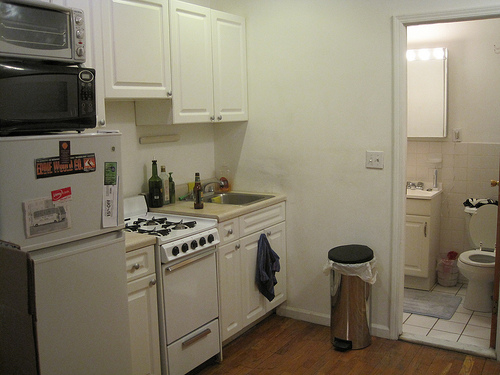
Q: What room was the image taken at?
A: It was taken at the kitchen.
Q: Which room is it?
A: It is a kitchen.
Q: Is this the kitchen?
A: Yes, it is the kitchen.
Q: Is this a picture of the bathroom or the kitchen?
A: It is showing the kitchen.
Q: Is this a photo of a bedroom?
A: No, the picture is showing a kitchen.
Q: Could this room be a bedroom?
A: No, it is a kitchen.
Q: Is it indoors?
A: Yes, it is indoors.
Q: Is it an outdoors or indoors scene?
A: It is indoors.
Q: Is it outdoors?
A: No, it is indoors.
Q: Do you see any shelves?
A: No, there are no shelves.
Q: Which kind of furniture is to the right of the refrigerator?
A: The pieces of furniture are cupboards.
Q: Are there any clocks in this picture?
A: No, there are no clocks.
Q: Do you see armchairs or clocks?
A: No, there are no clocks or armchairs.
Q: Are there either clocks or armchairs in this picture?
A: No, there are no clocks or armchairs.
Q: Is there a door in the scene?
A: Yes, there is a door.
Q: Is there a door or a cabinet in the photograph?
A: Yes, there is a door.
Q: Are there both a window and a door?
A: No, there is a door but no windows.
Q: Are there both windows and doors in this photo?
A: No, there is a door but no windows.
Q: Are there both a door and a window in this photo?
A: No, there is a door but no windows.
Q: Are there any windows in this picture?
A: No, there are no windows.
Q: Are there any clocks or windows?
A: No, there are no windows or clocks.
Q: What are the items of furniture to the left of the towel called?
A: The pieces of furniture are cupboards.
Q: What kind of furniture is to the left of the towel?
A: The pieces of furniture are cupboards.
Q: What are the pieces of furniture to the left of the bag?
A: The pieces of furniture are cupboards.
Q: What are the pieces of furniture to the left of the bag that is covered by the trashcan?
A: The pieces of furniture are cupboards.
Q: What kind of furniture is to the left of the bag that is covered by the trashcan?
A: The pieces of furniture are cupboards.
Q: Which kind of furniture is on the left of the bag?
A: The pieces of furniture are cupboards.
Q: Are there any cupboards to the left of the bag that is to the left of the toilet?
A: Yes, there are cupboards to the left of the bag.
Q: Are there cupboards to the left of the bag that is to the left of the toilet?
A: Yes, there are cupboards to the left of the bag.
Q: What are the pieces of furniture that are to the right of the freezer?
A: The pieces of furniture are cupboards.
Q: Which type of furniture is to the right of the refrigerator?
A: The pieces of furniture are cupboards.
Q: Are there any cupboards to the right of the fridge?
A: Yes, there are cupboards to the right of the fridge.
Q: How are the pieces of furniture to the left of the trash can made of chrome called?
A: The pieces of furniture are cupboards.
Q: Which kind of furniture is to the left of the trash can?
A: The pieces of furniture are cupboards.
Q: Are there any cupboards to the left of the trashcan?
A: Yes, there are cupboards to the left of the trashcan.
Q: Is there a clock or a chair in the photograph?
A: No, there are no chairs or clocks.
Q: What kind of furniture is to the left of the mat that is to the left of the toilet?
A: The piece of furniture is a cupboard.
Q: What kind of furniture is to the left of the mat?
A: The piece of furniture is a cupboard.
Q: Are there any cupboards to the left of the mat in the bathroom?
A: Yes, there is a cupboard to the left of the mat.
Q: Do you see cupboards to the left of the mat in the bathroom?
A: Yes, there is a cupboard to the left of the mat.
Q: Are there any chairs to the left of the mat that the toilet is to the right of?
A: No, there is a cupboard to the left of the mat.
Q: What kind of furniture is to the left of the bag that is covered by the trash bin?
A: The piece of furniture is a cupboard.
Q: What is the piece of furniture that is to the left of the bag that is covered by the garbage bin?
A: The piece of furniture is a cupboard.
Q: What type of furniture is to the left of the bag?
A: The piece of furniture is a cupboard.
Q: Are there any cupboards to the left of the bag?
A: Yes, there is a cupboard to the left of the bag.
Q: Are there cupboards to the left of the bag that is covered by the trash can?
A: Yes, there is a cupboard to the left of the bag.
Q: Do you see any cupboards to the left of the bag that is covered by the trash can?
A: Yes, there is a cupboard to the left of the bag.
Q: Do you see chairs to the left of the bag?
A: No, there is a cupboard to the left of the bag.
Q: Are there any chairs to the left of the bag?
A: No, there is a cupboard to the left of the bag.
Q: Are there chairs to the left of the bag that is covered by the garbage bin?
A: No, there is a cupboard to the left of the bag.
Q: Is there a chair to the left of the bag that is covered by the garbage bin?
A: No, there is a cupboard to the left of the bag.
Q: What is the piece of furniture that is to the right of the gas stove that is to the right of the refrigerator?
A: The piece of furniture is a cupboard.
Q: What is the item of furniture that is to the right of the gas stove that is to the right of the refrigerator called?
A: The piece of furniture is a cupboard.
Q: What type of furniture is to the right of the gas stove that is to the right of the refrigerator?
A: The piece of furniture is a cupboard.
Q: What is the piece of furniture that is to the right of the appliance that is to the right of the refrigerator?
A: The piece of furniture is a cupboard.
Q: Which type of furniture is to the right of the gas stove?
A: The piece of furniture is a cupboard.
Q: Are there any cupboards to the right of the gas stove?
A: Yes, there is a cupboard to the right of the gas stove.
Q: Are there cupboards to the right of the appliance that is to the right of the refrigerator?
A: Yes, there is a cupboard to the right of the gas stove.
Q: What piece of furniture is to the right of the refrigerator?
A: The piece of furniture is a cupboard.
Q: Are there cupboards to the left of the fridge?
A: No, the cupboard is to the right of the fridge.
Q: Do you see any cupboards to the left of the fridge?
A: No, the cupboard is to the right of the fridge.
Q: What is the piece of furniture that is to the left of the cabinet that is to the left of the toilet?
A: The piece of furniture is a cupboard.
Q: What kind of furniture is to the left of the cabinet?
A: The piece of furniture is a cupboard.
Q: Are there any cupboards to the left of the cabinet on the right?
A: Yes, there is a cupboard to the left of the cabinet.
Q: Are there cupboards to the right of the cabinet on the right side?
A: No, the cupboard is to the left of the cabinet.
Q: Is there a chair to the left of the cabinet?
A: No, there is a cupboard to the left of the cabinet.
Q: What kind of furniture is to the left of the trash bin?
A: The piece of furniture is a cupboard.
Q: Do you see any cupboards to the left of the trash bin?
A: Yes, there is a cupboard to the left of the trash bin.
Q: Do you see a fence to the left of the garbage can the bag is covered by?
A: No, there is a cupboard to the left of the trash can.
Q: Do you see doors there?
A: Yes, there is a door.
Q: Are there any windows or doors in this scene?
A: Yes, there is a door.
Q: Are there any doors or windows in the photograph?
A: Yes, there is a door.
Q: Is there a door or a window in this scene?
A: Yes, there is a door.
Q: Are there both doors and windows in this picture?
A: No, there is a door but no windows.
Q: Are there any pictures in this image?
A: No, there are no pictures.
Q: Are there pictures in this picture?
A: No, there are no pictures.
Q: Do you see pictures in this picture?
A: No, there are no pictures.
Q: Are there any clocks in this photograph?
A: No, there are no clocks.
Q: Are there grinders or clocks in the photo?
A: No, there are no clocks or grinders.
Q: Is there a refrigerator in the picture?
A: Yes, there is a refrigerator.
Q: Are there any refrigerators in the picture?
A: Yes, there is a refrigerator.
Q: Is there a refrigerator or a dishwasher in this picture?
A: Yes, there is a refrigerator.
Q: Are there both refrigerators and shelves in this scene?
A: No, there is a refrigerator but no shelves.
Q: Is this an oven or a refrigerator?
A: This is a refrigerator.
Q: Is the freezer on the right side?
A: No, the freezer is on the left of the image.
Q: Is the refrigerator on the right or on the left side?
A: The refrigerator is on the left of the image.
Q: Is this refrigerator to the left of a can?
A: No, the refrigerator is to the left of a bottle.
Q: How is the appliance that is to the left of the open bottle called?
A: The appliance is a refrigerator.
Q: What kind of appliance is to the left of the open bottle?
A: The appliance is a refrigerator.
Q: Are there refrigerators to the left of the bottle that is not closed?
A: Yes, there is a refrigerator to the left of the bottle.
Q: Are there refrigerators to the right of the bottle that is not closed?
A: No, the refrigerator is to the left of the bottle.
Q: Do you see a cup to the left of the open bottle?
A: No, there is a refrigerator to the left of the bottle.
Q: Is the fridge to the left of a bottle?
A: Yes, the fridge is to the left of a bottle.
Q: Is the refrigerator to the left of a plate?
A: No, the refrigerator is to the left of a bottle.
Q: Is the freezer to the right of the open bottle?
A: No, the freezer is to the left of the bottle.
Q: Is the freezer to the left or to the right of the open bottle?
A: The freezer is to the left of the bottle.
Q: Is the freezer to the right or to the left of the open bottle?
A: The freezer is to the left of the bottle.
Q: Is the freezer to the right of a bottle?
A: No, the freezer is to the left of a bottle.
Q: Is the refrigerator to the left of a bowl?
A: No, the refrigerator is to the left of a bottle.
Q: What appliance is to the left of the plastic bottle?
A: The appliance is a refrigerator.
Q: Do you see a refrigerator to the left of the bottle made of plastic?
A: Yes, there is a refrigerator to the left of the bottle.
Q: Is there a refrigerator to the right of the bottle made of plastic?
A: No, the refrigerator is to the left of the bottle.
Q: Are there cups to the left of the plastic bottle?
A: No, there is a refrigerator to the left of the bottle.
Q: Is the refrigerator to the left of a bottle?
A: Yes, the refrigerator is to the left of a bottle.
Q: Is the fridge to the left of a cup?
A: No, the fridge is to the left of a bottle.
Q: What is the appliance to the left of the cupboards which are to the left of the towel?
A: The appliance is a refrigerator.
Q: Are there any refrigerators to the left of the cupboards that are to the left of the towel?
A: Yes, there is a refrigerator to the left of the cupboards.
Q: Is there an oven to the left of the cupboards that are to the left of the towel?
A: No, there is a refrigerator to the left of the cupboards.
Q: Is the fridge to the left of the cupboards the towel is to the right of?
A: Yes, the fridge is to the left of the cupboards.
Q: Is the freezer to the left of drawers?
A: No, the freezer is to the left of the cupboards.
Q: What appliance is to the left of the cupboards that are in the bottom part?
A: The appliance is a refrigerator.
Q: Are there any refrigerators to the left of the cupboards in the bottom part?
A: Yes, there is a refrigerator to the left of the cupboards.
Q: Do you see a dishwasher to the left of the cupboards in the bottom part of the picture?
A: No, there is a refrigerator to the left of the cupboards.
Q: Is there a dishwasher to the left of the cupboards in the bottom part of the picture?
A: No, there is a refrigerator to the left of the cupboards.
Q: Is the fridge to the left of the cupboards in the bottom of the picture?
A: Yes, the fridge is to the left of the cupboards.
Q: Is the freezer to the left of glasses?
A: No, the freezer is to the left of the cupboards.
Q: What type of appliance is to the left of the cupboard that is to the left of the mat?
A: The appliance is a refrigerator.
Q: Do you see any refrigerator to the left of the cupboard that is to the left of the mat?
A: Yes, there is a refrigerator to the left of the cupboard.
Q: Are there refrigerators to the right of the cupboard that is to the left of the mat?
A: No, the refrigerator is to the left of the cupboard.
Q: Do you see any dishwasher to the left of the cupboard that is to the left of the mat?
A: No, there is a refrigerator to the left of the cupboard.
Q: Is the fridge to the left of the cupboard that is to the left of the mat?
A: Yes, the fridge is to the left of the cupboard.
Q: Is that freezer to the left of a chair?
A: No, the freezer is to the left of the cupboard.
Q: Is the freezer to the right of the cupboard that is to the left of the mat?
A: No, the freezer is to the left of the cupboard.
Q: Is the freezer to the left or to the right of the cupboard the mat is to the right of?
A: The freezer is to the left of the cupboard.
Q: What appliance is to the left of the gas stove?
A: The appliance is a refrigerator.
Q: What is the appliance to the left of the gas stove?
A: The appliance is a refrigerator.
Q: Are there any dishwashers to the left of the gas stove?
A: No, there is a refrigerator to the left of the gas stove.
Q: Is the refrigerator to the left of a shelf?
A: No, the refrigerator is to the left of the gas stove.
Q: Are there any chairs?
A: No, there are no chairs.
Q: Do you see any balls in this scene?
A: No, there are no balls.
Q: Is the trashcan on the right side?
A: Yes, the trashcan is on the right of the image.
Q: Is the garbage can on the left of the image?
A: No, the garbage can is on the right of the image.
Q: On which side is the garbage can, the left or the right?
A: The garbage can is on the right of the image.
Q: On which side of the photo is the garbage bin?
A: The garbage bin is on the right of the image.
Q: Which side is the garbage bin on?
A: The garbage bin is on the right of the image.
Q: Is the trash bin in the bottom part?
A: Yes, the trash bin is in the bottom of the image.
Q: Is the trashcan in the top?
A: No, the trashcan is in the bottom of the image.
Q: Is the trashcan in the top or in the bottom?
A: The trashcan is in the bottom of the image.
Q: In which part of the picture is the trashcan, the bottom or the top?
A: The trashcan is in the bottom of the image.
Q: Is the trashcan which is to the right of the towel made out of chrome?
A: Yes, the trash can is made of chrome.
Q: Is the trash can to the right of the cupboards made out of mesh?
A: No, the trash bin is made of chrome.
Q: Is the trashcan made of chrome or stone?
A: The trashcan is made of chrome.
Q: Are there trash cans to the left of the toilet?
A: Yes, there is a trash can to the left of the toilet.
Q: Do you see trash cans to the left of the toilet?
A: Yes, there is a trash can to the left of the toilet.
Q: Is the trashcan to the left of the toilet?
A: Yes, the trashcan is to the left of the toilet.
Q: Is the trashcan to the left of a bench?
A: No, the trashcan is to the left of the toilet.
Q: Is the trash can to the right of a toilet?
A: No, the trash can is to the left of a toilet.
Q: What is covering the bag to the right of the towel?
A: The trash bin is covering the bag.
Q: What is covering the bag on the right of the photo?
A: The trash bin is covering the bag.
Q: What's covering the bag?
A: The trash bin is covering the bag.